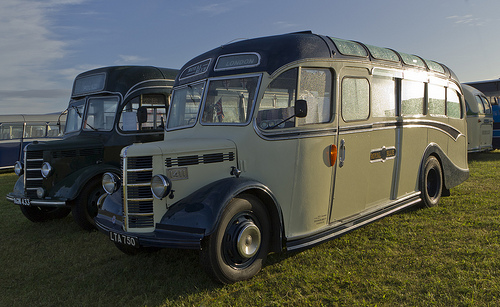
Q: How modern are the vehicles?
A: They're vintage.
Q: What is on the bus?
A: Tires.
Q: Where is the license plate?
A: On the front of the bus.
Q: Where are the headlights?
A: On the front of the bus.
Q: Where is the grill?
A: On the front of the bus.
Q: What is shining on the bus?
A: The sun.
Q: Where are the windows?
A: On the top part of the bus.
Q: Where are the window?
A: Around the bus.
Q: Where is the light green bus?
A: Next to the black bus.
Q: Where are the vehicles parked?
A: Grass.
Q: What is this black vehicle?
A: Van.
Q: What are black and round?
A: Wheels.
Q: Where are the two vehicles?
A: Parked in the grass field.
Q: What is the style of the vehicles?
A: Retro.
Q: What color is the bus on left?
A: Black.